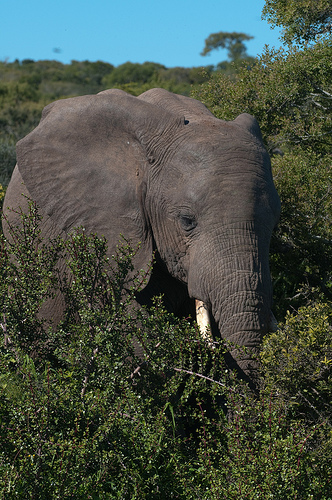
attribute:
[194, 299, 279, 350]
tusks — white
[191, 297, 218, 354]
tusk — white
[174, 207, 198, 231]
eye — open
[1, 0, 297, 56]
sky — blue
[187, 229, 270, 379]
trunk — wrinkled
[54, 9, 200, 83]
sky — blue, cloudless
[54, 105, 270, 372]
elephants — large, grey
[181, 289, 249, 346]
tusk — ivory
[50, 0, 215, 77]
sky — bright, clear, blue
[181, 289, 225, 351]
tusk — white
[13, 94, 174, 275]
ear — large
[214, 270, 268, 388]
trunk — downward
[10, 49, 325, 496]
bushes — green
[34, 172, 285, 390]
elephant's — gray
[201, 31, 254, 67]
tree — green  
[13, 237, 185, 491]
bushes — green 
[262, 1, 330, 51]
tree — green 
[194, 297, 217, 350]
tusk — white 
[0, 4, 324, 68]
sky — blue 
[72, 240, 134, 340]
leaves — green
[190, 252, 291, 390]
elephant — gray 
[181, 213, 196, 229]
eye — dark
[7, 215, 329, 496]
bushes — green 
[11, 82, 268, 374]
elephant — Gray , large 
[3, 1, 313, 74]
sky — blue 